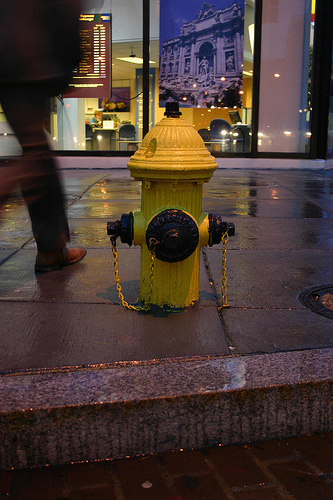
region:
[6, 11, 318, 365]
close-up of a fire hydrant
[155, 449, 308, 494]
red bricks on the street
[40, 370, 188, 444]
curb at the end of the sidewalk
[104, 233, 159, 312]
chain on the fire hydrant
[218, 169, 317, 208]
wet sidewalk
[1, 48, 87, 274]
blurred image of man walking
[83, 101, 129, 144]
woman at a desk with two chairs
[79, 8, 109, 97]
informational sign on a business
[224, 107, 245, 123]
lap top on a desk inside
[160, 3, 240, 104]
poster of a famous monument in Rome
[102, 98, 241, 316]
a yellow and black fire hydrant.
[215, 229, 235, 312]
a yellow fire hydrant chain.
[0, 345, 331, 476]
a curb near a sidewalk.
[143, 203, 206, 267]
the side of a fire hydrant.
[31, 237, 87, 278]
a right foot shoe.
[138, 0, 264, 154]
a large window on the front of a building.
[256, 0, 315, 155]
a large reflective window.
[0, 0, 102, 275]
a man walking near a fire hydrant.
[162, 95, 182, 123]
the cap on a fire hydrant.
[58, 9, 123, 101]
a sign in a window.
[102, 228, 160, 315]
Yellow chain on a fire hydant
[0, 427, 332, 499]
Roadway made of bricks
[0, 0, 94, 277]
Person walking on a sidewalk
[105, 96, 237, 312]
Old yellow and black fire hydrant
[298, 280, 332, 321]
Man hole on the sidewalk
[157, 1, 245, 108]
Picture of a building in the window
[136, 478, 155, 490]
Used gum pressed on the street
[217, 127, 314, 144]
Car headlights reflected in the window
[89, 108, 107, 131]
Person sitting at a desk in an office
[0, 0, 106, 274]
Person wearing a brown boot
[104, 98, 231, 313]
yellow and black fire hydrant on the sidewalk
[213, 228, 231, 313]
chain from the fire hydrant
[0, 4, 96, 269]
person walking on the sidewalk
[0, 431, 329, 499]
brick material on the street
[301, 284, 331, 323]
partial view of a manhole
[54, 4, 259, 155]
glass window on a store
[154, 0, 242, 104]
a banner of a building monument on the window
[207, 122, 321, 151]
lights reflecting on the window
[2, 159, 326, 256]
the sidewalk is wet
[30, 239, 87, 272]
the man is wearing a brown shoe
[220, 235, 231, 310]
bright yellow chain on hydrant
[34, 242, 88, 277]
brown boot on sidewalk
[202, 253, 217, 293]
crack in sidewalk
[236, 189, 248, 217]
light reflecting on sidwalk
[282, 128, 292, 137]
light reflecting in window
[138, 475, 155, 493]
gum stuck to bricks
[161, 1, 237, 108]
large sign in window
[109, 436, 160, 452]
drip marks along side walk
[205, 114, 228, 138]
bright blue chair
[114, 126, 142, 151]
chair in front of desk